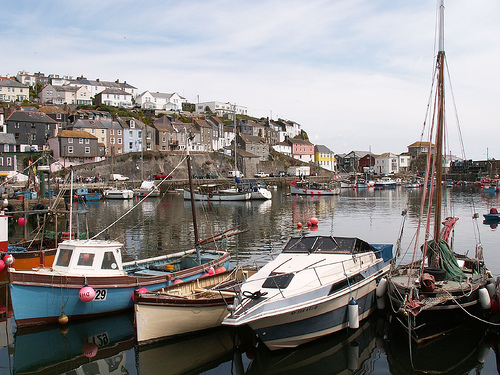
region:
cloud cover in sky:
[0, 1, 497, 151]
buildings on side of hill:
[1, 72, 341, 182]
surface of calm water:
[42, 185, 498, 263]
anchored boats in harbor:
[2, 172, 498, 373]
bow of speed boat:
[220, 236, 391, 354]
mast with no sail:
[399, 0, 476, 275]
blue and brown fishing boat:
[8, 240, 227, 329]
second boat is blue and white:
[219, 225, 401, 358]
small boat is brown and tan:
[126, 264, 267, 346]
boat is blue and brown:
[11, 226, 235, 332]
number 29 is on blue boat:
[87, 283, 108, 308]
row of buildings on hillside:
[4, 68, 344, 183]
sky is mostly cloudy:
[0, 0, 497, 161]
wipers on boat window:
[326, 233, 341, 249]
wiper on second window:
[286, 237, 306, 248]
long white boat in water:
[179, 182, 252, 202]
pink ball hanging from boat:
[75, 283, 96, 303]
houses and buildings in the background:
[0, 64, 435, 184]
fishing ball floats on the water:
[289, 213, 321, 230]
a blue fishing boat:
[3, 142, 236, 332]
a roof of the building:
[406, 138, 437, 149]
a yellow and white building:
[311, 143, 336, 173]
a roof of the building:
[3, 107, 59, 125]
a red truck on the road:
[148, 169, 174, 182]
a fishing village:
[0, 65, 497, 373]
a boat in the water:
[284, 175, 346, 200]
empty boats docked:
[1, 140, 499, 357]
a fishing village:
[3, 6, 498, 370]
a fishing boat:
[381, 44, 497, 354]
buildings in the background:
[1, 66, 426, 178]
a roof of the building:
[56, 128, 99, 141]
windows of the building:
[63, 136, 94, 156]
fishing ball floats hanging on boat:
[46, 283, 100, 329]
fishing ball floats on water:
[290, 212, 327, 232]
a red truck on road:
[149, 169, 175, 181]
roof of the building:
[314, 143, 334, 154]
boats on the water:
[32, 203, 498, 370]